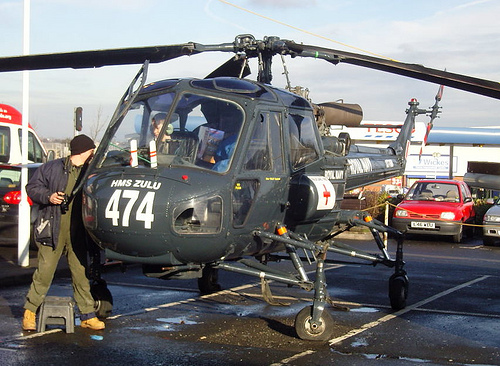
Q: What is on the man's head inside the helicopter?
A: Headgear.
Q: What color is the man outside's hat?
A: Black.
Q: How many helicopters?
A: One.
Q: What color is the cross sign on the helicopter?
A: Red.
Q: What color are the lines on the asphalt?
A: White.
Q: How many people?
A: Two.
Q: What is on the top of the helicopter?
A: Propellers.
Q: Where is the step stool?
A: Under the man.